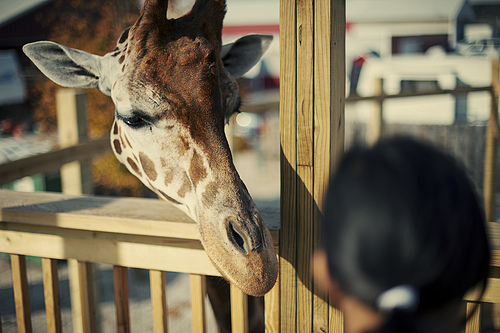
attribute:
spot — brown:
[110, 120, 122, 136]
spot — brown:
[110, 138, 124, 157]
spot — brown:
[124, 134, 134, 150]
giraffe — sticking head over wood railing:
[22, 2, 279, 297]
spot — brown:
[120, 131, 137, 151]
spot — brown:
[125, 155, 142, 178]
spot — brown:
[135, 150, 158, 186]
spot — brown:
[162, 163, 177, 187]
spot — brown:
[174, 169, 193, 202]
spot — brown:
[186, 147, 210, 190]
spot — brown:
[176, 132, 192, 158]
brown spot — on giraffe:
[135, 151, 160, 181]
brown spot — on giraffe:
[158, 165, 177, 189]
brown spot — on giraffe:
[190, 157, 205, 180]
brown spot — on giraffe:
[189, 155, 201, 177]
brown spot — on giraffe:
[145, 156, 153, 175]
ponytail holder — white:
[375, 280, 415, 313]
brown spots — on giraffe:
[190, 157, 206, 177]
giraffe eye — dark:
[119, 112, 155, 129]